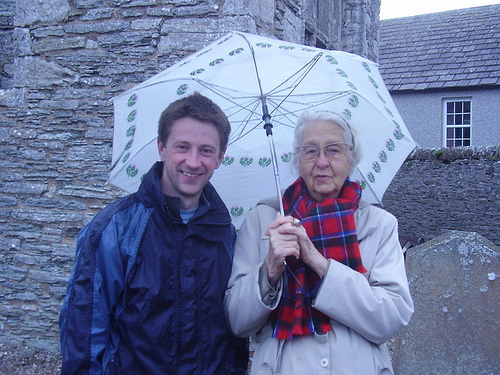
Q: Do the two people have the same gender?
A: No, they are both male and female.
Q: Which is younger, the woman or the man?
A: The man is younger than the woman.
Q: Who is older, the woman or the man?
A: The woman is older than the man.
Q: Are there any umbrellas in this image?
A: Yes, there is an umbrella.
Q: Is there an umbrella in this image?
A: Yes, there is an umbrella.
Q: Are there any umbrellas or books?
A: Yes, there is an umbrella.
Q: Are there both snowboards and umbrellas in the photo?
A: No, there is an umbrella but no snowboards.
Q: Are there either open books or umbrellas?
A: Yes, there is an open umbrella.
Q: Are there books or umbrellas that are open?
A: Yes, the umbrella is open.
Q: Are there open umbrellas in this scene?
A: Yes, there is an open umbrella.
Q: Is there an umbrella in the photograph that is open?
A: Yes, there is an umbrella that is open.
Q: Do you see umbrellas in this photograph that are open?
A: Yes, there is an umbrella that is open.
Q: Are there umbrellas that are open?
A: Yes, there is an umbrella that is open.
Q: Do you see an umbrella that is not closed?
A: Yes, there is a open umbrella.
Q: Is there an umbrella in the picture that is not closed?
A: Yes, there is a open umbrella.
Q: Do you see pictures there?
A: No, there are no pictures.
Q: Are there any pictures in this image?
A: No, there are no pictures.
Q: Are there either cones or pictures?
A: No, there are no pictures or cones.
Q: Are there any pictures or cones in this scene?
A: No, there are no pictures or cones.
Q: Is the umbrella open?
A: Yes, the umbrella is open.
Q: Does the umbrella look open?
A: Yes, the umbrella is open.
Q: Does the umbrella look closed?
A: No, the umbrella is open.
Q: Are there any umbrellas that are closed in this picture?
A: No, there is an umbrella but it is open.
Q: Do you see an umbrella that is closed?
A: No, there is an umbrella but it is open.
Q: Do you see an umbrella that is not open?
A: No, there is an umbrella but it is open.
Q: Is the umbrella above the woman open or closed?
A: The umbrella is open.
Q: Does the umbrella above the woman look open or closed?
A: The umbrella is open.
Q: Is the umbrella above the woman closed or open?
A: The umbrella is open.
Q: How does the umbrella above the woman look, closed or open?
A: The umbrella is open.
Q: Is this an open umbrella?
A: Yes, this is an open umbrella.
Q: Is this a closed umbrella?
A: No, this is an open umbrella.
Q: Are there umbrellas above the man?
A: Yes, there is an umbrella above the man.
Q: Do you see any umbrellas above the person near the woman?
A: Yes, there is an umbrella above the man.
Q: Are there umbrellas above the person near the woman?
A: Yes, there is an umbrella above the man.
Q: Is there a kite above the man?
A: No, there is an umbrella above the man.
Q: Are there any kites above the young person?
A: No, there is an umbrella above the man.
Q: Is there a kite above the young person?
A: No, there is an umbrella above the man.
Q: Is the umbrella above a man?
A: Yes, the umbrella is above a man.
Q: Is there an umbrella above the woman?
A: Yes, there is an umbrella above the woman.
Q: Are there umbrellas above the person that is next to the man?
A: Yes, there is an umbrella above the woman.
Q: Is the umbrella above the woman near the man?
A: Yes, the umbrella is above the woman.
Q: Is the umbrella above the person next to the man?
A: Yes, the umbrella is above the woman.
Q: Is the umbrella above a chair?
A: No, the umbrella is above the woman.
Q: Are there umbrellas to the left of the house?
A: Yes, there is an umbrella to the left of the house.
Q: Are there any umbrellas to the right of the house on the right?
A: No, the umbrella is to the left of the house.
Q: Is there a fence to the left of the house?
A: No, there is an umbrella to the left of the house.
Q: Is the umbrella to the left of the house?
A: Yes, the umbrella is to the left of the house.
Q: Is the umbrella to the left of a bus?
A: No, the umbrella is to the left of the house.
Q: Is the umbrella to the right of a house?
A: No, the umbrella is to the left of a house.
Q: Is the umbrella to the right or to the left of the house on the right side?
A: The umbrella is to the left of the house.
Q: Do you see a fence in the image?
A: No, there are no fences.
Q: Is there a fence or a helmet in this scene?
A: No, there are no fences or helmets.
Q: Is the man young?
A: Yes, the man is young.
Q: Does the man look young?
A: Yes, the man is young.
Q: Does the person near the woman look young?
A: Yes, the man is young.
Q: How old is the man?
A: The man is young.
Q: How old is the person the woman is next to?
A: The man is young.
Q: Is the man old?
A: No, the man is young.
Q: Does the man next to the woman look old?
A: No, the man is young.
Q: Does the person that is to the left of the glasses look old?
A: No, the man is young.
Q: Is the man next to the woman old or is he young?
A: The man is young.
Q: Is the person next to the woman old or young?
A: The man is young.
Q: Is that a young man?
A: Yes, that is a young man.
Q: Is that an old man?
A: No, that is a young man.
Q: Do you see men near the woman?
A: Yes, there is a man near the woman.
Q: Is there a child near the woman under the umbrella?
A: No, there is a man near the woman.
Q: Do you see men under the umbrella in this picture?
A: Yes, there is a man under the umbrella.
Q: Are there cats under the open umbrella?
A: No, there is a man under the umbrella.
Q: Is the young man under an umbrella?
A: Yes, the man is under an umbrella.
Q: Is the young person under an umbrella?
A: Yes, the man is under an umbrella.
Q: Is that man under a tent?
A: No, the man is under an umbrella.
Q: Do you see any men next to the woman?
A: Yes, there is a man next to the woman.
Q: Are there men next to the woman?
A: Yes, there is a man next to the woman.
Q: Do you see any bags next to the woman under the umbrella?
A: No, there is a man next to the woman.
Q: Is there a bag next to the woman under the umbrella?
A: No, there is a man next to the woman.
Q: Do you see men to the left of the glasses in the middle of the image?
A: Yes, there is a man to the left of the glasses.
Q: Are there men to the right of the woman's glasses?
A: No, the man is to the left of the glasses.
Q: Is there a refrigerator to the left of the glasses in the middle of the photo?
A: No, there is a man to the left of the glasses.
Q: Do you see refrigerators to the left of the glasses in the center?
A: No, there is a man to the left of the glasses.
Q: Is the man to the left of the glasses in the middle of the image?
A: Yes, the man is to the left of the glasses.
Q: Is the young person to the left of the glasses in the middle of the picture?
A: Yes, the man is to the left of the glasses.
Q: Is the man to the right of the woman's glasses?
A: No, the man is to the left of the glasses.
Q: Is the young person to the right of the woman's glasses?
A: No, the man is to the left of the glasses.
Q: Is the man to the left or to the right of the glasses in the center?
A: The man is to the left of the glasses.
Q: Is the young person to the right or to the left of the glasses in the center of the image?
A: The man is to the left of the glasses.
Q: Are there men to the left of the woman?
A: Yes, there is a man to the left of the woman.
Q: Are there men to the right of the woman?
A: No, the man is to the left of the woman.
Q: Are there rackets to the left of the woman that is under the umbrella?
A: No, there is a man to the left of the woman.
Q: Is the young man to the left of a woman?
A: Yes, the man is to the left of a woman.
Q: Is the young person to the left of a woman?
A: Yes, the man is to the left of a woman.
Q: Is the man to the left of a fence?
A: No, the man is to the left of a woman.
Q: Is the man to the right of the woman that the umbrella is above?
A: No, the man is to the left of the woman.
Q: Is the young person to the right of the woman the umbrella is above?
A: No, the man is to the left of the woman.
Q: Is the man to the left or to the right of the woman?
A: The man is to the left of the woman.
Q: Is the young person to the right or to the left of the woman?
A: The man is to the left of the woman.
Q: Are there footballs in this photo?
A: No, there are no footballs.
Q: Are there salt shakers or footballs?
A: No, there are no footballs or salt shakers.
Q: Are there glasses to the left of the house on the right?
A: Yes, there are glasses to the left of the house.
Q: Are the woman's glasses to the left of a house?
A: Yes, the glasses are to the left of a house.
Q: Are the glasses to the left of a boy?
A: No, the glasses are to the left of a house.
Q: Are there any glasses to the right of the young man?
A: Yes, there are glasses to the right of the man.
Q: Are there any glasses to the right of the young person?
A: Yes, there are glasses to the right of the man.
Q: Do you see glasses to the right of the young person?
A: Yes, there are glasses to the right of the man.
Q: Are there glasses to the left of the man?
A: No, the glasses are to the right of the man.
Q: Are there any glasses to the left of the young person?
A: No, the glasses are to the right of the man.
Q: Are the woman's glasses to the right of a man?
A: Yes, the glasses are to the right of a man.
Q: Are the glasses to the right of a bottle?
A: No, the glasses are to the right of a man.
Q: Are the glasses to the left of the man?
A: No, the glasses are to the right of the man.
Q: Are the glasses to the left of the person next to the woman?
A: No, the glasses are to the right of the man.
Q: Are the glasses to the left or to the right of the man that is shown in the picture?
A: The glasses are to the right of the man.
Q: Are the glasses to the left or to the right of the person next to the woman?
A: The glasses are to the right of the man.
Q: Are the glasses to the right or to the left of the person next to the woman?
A: The glasses are to the right of the man.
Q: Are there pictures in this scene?
A: No, there are no pictures.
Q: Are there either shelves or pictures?
A: No, there are no pictures or shelves.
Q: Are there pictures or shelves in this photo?
A: No, there are no pictures or shelves.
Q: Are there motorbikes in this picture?
A: No, there are no motorbikes.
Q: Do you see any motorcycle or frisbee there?
A: No, there are no motorcycles or frisbees.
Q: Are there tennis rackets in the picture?
A: No, there are no tennis rackets.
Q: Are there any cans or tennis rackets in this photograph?
A: No, there are no tennis rackets or cans.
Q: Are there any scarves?
A: Yes, there is a scarf.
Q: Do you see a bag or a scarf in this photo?
A: Yes, there is a scarf.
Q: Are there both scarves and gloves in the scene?
A: No, there is a scarf but no gloves.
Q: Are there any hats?
A: No, there are no hats.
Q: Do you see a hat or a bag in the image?
A: No, there are no hats or bags.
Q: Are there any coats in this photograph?
A: Yes, there is a coat.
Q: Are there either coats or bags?
A: Yes, there is a coat.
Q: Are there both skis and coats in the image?
A: No, there is a coat but no skis.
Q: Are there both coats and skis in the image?
A: No, there is a coat but no skis.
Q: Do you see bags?
A: No, there are no bags.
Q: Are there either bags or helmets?
A: No, there are no bags or helmets.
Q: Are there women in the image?
A: Yes, there is a woman.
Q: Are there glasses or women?
A: Yes, there is a woman.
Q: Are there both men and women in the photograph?
A: Yes, there are both a woman and a man.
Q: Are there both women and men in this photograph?
A: Yes, there are both a woman and a man.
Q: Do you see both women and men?
A: Yes, there are both a woman and a man.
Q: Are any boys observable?
A: No, there are no boys.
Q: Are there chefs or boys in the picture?
A: No, there are no boys or chefs.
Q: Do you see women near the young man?
A: Yes, there is a woman near the man.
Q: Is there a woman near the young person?
A: Yes, there is a woman near the man.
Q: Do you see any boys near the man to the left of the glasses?
A: No, there is a woman near the man.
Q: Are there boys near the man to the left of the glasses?
A: No, there is a woman near the man.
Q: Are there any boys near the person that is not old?
A: No, there is a woman near the man.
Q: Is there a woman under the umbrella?
A: Yes, there is a woman under the umbrella.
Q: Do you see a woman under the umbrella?
A: Yes, there is a woman under the umbrella.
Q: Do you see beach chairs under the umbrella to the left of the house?
A: No, there is a woman under the umbrella.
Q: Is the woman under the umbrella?
A: Yes, the woman is under the umbrella.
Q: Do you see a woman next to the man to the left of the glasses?
A: Yes, there is a woman next to the man.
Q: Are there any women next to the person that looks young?
A: Yes, there is a woman next to the man.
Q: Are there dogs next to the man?
A: No, there is a woman next to the man.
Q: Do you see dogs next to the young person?
A: No, there is a woman next to the man.